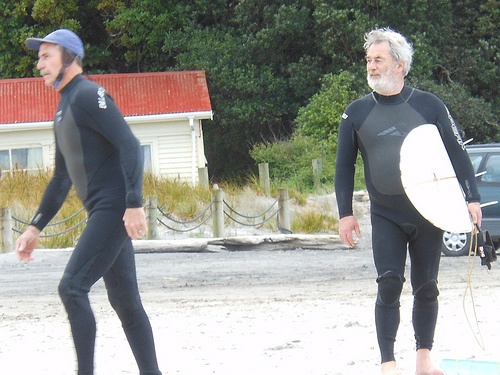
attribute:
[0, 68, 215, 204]
building — white, red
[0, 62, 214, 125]
roof — red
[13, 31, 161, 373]
man — walking, black, surfing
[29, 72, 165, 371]
swim suit — black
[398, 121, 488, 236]
surf board — white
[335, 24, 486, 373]
man — walking, older, surfing, shoeless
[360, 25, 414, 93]
hair — grey, white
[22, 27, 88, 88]
hat — blue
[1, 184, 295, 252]
fence — metal, beach, wood, chain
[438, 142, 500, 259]
vehicle — green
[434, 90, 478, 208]
arm — man's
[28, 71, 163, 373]
wet suit — long sleeve, black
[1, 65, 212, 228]
house — white, small, red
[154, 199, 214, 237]
links — chain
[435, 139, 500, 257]
car — parked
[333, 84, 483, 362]
wet suit — black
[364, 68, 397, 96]
beard — grey, white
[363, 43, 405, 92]
face — man's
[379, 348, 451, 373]
feet — bare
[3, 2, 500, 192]
trees — green, leafy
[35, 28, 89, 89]
head — man's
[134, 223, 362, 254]
wood — long, dead, drift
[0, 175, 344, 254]
grass — green, tall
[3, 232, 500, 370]
road — sandy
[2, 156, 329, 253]
poles — wooden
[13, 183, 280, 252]
barriers — rope